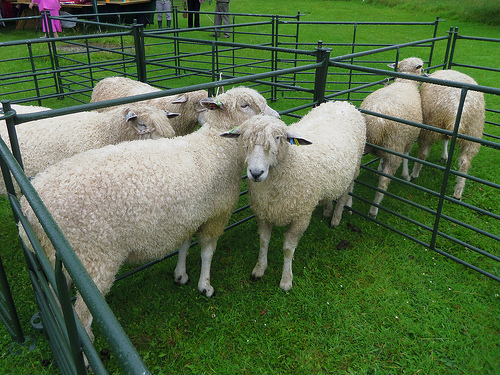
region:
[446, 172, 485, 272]
the cage is green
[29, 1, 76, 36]
the dress is pink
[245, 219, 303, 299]
the sheep has front legs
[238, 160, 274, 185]
the sheep has a nose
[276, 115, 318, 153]
the sheep has an ear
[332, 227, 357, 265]
sheep manure is on the ground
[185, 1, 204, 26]
the pants are black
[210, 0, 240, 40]
the pants are gray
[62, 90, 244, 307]
the sheep is big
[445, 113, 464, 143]
the sheep has a tail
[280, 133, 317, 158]
the ear has tags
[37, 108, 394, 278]
the sheep are two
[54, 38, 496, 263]
the sheep are six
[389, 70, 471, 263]
the bars are mettalic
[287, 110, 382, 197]
the wool is white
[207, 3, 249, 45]
the pant is grey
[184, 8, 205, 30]
the pants are black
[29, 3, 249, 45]
four people are in the field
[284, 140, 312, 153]
the tag is green and blue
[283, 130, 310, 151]
blue and yellow tags on sheep's ear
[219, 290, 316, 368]
green grass in small sheep pen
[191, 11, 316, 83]
green metal railing of sheep pens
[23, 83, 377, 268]
sheep in pens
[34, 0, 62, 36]
person wearing a pink dress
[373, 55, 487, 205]
back of two sheep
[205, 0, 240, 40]
person wearing grey pants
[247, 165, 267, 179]
sheep nose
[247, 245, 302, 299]
two sheep hooves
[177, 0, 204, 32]
person wearing black pants behind the pens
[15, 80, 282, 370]
a standing white sheep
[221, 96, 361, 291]
a standing white sheep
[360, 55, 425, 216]
a standing white sheep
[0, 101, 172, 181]
a standing white sheepa standing white sheep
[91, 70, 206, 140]
a standing white sheep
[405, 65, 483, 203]
a standing white sheep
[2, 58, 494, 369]
a green metal fence pen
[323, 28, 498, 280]
a green metal fence pen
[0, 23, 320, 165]
a green metal fence pen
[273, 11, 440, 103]
an open metal gate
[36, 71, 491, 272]
Sheep in pens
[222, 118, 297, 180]
Sheep has long hair hanging in face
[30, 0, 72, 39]
Someone dressed in pink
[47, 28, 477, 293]
There are six sheep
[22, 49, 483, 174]
Two sheep in each pen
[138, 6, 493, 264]
Sheep enclosure is made of steel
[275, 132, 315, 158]
One sheeps ear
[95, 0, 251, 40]
people in the background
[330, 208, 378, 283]
The sheep pooped on the ground